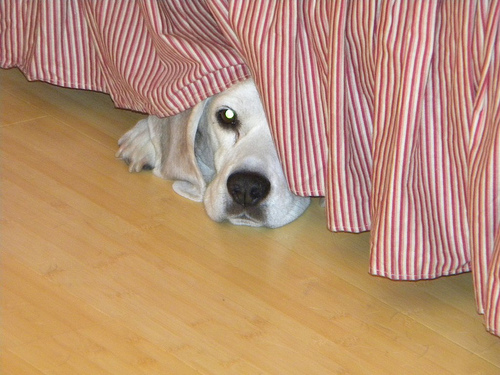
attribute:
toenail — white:
[122, 160, 147, 178]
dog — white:
[108, 69, 311, 225]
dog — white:
[110, 71, 330, 238]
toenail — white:
[110, 136, 128, 157]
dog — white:
[115, 67, 304, 230]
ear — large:
[143, 92, 209, 201]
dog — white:
[102, 71, 344, 261]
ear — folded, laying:
[125, 115, 255, 221]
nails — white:
[95, 136, 167, 190]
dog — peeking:
[146, 88, 286, 220]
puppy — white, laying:
[121, 106, 308, 226]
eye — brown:
[213, 105, 237, 132]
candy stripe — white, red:
[357, 28, 437, 206]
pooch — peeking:
[113, 79, 318, 229]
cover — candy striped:
[3, 3, 494, 338]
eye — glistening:
[212, 104, 245, 134]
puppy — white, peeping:
[113, 77, 313, 229]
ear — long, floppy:
[148, 88, 211, 207]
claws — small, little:
[116, 122, 143, 173]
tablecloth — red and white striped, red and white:
[0, 0, 500, 338]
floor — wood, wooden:
[0, 63, 499, 373]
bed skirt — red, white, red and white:
[0, 0, 498, 335]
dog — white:
[115, 74, 314, 232]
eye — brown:
[216, 104, 246, 135]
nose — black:
[224, 165, 277, 208]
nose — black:
[223, 169, 275, 209]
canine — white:
[112, 75, 318, 231]